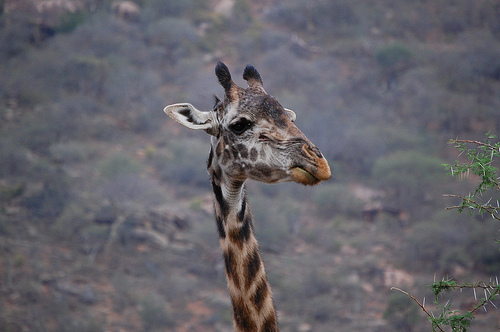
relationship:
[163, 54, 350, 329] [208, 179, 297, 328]
giraffe has neck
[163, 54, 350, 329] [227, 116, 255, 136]
giraffe has eye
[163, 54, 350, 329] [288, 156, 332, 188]
giraffe has closed mouth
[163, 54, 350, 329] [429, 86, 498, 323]
giraffe front tree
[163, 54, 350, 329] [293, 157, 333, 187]
giraffe has mouth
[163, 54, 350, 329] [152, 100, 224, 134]
giraffe has ear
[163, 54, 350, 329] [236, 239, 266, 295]
giraffe has spot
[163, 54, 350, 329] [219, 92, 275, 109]
giraffe has forehead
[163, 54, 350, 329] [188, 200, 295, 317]
giraffe has neck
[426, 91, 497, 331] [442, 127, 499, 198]
tree has leaves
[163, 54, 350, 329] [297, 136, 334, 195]
giraffe has nose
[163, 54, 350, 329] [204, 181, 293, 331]
giraffe has throat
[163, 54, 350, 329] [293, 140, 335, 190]
giraffe has nose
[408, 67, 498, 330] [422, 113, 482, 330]
trees front tree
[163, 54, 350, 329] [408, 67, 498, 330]
giraffe looks trees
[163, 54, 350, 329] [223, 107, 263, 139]
giraffe has eyes